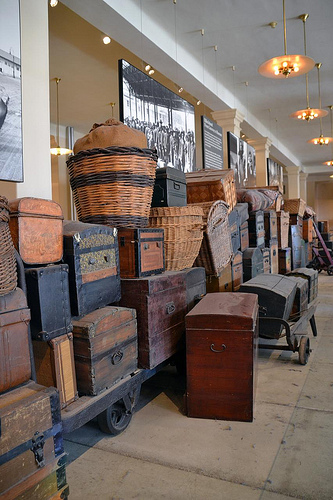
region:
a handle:
[209, 344, 226, 357]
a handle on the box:
[112, 348, 125, 363]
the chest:
[187, 321, 251, 416]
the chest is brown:
[188, 318, 251, 417]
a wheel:
[296, 336, 315, 365]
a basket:
[91, 149, 150, 219]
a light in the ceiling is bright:
[294, 110, 323, 120]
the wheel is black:
[102, 412, 125, 432]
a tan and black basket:
[63, 141, 158, 222]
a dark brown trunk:
[183, 286, 259, 419]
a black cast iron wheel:
[102, 394, 144, 433]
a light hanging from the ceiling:
[261, 7, 313, 76]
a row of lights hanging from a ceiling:
[257, 0, 332, 170]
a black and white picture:
[122, 62, 194, 161]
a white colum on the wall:
[247, 133, 276, 185]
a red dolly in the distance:
[308, 218, 331, 273]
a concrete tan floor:
[194, 421, 308, 490]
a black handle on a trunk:
[111, 351, 128, 370]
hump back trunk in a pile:
[72, 221, 127, 313]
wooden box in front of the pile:
[182, 268, 260, 432]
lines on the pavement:
[259, 434, 322, 496]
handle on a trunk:
[102, 345, 134, 371]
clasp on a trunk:
[23, 428, 60, 472]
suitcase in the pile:
[36, 327, 92, 424]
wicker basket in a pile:
[201, 200, 237, 271]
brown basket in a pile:
[156, 211, 210, 272]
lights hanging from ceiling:
[259, 2, 331, 144]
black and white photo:
[118, 58, 195, 168]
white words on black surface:
[201, 116, 222, 168]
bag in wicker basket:
[67, 120, 159, 227]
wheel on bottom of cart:
[61, 371, 149, 438]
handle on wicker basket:
[154, 207, 205, 266]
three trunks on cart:
[251, 269, 322, 363]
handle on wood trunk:
[92, 309, 139, 389]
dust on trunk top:
[191, 292, 255, 315]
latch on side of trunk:
[29, 432, 46, 468]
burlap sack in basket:
[61, 119, 142, 160]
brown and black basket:
[63, 141, 159, 209]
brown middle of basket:
[75, 179, 145, 216]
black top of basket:
[52, 148, 155, 165]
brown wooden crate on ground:
[174, 293, 264, 439]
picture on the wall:
[0, 67, 29, 104]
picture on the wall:
[111, 61, 200, 167]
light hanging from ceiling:
[255, 49, 309, 92]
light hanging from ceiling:
[293, 101, 323, 127]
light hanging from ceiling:
[312, 134, 331, 149]